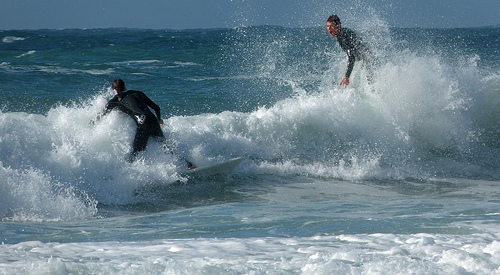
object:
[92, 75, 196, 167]
guy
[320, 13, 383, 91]
guy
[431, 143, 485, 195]
ground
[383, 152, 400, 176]
ground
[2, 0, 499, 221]
spray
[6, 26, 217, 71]
calm water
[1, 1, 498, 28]
sky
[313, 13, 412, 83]
wetsuit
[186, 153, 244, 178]
board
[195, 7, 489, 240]
ocean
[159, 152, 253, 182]
surfboard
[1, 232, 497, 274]
foam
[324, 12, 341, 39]
head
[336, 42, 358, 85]
arm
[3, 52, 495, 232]
wave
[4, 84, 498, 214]
background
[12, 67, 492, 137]
distance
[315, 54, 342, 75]
head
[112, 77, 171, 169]
wetsuit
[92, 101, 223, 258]
camera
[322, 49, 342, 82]
visible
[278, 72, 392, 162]
visible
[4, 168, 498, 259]
ocean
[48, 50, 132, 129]
skyline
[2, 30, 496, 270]
water